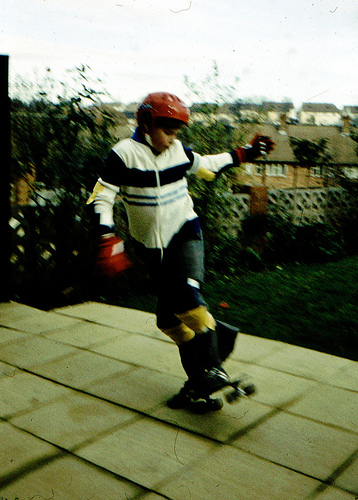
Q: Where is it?
A: This is at the backyard.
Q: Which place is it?
A: It is a backyard.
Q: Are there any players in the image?
A: No, there are no players.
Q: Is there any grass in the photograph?
A: Yes, there is grass.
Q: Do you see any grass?
A: Yes, there is grass.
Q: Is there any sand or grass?
A: Yes, there is grass.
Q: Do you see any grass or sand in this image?
A: Yes, there is grass.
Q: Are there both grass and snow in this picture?
A: No, there is grass but no snow.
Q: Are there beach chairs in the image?
A: No, there are no beach chairs.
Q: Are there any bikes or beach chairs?
A: No, there are no beach chairs or bikes.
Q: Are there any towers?
A: No, there are no towers.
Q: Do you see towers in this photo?
A: No, there are no towers.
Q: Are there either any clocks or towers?
A: No, there are no towers or clocks.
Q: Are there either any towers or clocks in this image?
A: No, there are no towers or clocks.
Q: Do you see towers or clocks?
A: No, there are no towers or clocks.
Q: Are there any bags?
A: No, there are no bags.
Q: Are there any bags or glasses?
A: No, there are no bags or glasses.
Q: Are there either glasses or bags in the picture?
A: No, there are no bags or glasses.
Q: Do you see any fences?
A: Yes, there is a fence.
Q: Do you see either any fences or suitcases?
A: Yes, there is a fence.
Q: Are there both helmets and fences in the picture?
A: Yes, there are both a fence and a helmet.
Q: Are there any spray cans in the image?
A: No, there are no spray cans.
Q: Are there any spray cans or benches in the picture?
A: No, there are no spray cans or benches.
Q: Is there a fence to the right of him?
A: Yes, there is a fence to the right of the boy.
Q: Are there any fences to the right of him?
A: Yes, there is a fence to the right of the boy.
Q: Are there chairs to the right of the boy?
A: No, there is a fence to the right of the boy.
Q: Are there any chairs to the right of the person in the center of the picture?
A: No, there is a fence to the right of the boy.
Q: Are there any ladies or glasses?
A: No, there are no glasses or ladies.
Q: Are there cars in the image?
A: No, there are no cars.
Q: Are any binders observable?
A: No, there are no binders.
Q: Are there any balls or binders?
A: No, there are no binders or balls.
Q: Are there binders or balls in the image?
A: No, there are no binders or balls.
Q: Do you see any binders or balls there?
A: No, there are no binders or balls.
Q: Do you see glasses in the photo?
A: No, there are no glasses.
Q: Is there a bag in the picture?
A: No, there are no bags.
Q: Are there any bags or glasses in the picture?
A: No, there are no bags or glasses.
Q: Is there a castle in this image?
A: No, there are no castles.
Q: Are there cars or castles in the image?
A: No, there are no castles or cars.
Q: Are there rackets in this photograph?
A: No, there are no rackets.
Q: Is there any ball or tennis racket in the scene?
A: No, there are no rackets or balls.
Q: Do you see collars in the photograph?
A: Yes, there is a collar.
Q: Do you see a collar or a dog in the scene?
A: Yes, there is a collar.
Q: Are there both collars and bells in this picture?
A: No, there is a collar but no bells.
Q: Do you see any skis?
A: No, there are no skis.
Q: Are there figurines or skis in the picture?
A: No, there are no skis or figurines.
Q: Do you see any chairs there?
A: No, there are no chairs.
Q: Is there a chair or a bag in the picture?
A: No, there are no chairs or bags.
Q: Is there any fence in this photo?
A: Yes, there is a fence.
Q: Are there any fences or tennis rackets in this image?
A: Yes, there is a fence.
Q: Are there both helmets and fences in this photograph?
A: Yes, there are both a fence and a helmet.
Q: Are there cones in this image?
A: No, there are no cones.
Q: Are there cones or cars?
A: No, there are no cones or cars.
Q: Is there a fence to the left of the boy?
A: Yes, there is a fence to the left of the boy.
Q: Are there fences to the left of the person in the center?
A: Yes, there is a fence to the left of the boy.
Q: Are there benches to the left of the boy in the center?
A: No, there is a fence to the left of the boy.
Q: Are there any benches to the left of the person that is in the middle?
A: No, there is a fence to the left of the boy.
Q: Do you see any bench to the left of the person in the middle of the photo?
A: No, there is a fence to the left of the boy.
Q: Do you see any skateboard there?
A: Yes, there is a skateboard.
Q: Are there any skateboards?
A: Yes, there is a skateboard.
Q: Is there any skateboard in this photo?
A: Yes, there is a skateboard.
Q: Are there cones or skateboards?
A: Yes, there is a skateboard.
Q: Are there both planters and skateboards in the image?
A: No, there is a skateboard but no planters.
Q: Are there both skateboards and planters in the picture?
A: No, there is a skateboard but no planters.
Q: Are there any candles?
A: No, there are no candles.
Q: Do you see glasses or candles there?
A: No, there are no candles or glasses.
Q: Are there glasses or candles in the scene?
A: No, there are no candles or glasses.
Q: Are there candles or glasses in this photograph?
A: No, there are no candles or glasses.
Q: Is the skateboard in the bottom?
A: Yes, the skateboard is in the bottom of the image.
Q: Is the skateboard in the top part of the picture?
A: No, the skateboard is in the bottom of the image.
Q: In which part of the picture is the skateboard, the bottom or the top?
A: The skateboard is in the bottom of the image.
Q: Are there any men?
A: No, there are no men.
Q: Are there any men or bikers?
A: No, there are no men or bikers.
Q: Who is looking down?
A: The boy is looking down.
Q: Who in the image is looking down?
A: The boy is looking down.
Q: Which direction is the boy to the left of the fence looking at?
A: The boy is looking down.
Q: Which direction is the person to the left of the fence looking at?
A: The boy is looking down.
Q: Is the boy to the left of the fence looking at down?
A: Yes, the boy is looking down.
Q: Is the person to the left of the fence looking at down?
A: Yes, the boy is looking down.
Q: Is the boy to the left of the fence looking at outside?
A: No, the boy is looking down.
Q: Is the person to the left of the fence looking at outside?
A: No, the boy is looking down.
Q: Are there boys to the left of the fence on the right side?
A: Yes, there is a boy to the left of the fence.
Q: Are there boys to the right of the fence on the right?
A: No, the boy is to the left of the fence.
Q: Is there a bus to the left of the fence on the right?
A: No, there is a boy to the left of the fence.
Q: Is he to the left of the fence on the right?
A: Yes, the boy is to the left of the fence.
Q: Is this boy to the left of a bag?
A: No, the boy is to the left of the fence.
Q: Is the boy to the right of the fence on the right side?
A: No, the boy is to the left of the fence.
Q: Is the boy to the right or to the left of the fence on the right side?
A: The boy is to the left of the fence.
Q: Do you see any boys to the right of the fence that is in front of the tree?
A: Yes, there is a boy to the right of the fence.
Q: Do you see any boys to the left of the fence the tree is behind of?
A: No, the boy is to the right of the fence.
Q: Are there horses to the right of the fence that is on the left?
A: No, there is a boy to the right of the fence.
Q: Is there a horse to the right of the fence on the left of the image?
A: No, there is a boy to the right of the fence.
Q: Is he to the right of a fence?
A: Yes, the boy is to the right of a fence.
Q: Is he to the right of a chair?
A: No, the boy is to the right of a fence.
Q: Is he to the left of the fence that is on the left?
A: No, the boy is to the right of the fence.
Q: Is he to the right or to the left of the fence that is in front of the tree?
A: The boy is to the right of the fence.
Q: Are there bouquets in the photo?
A: No, there are no bouquets.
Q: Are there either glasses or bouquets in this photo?
A: No, there are no bouquets or glasses.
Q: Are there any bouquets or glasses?
A: No, there are no bouquets or glasses.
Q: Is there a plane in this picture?
A: No, there are no airplanes.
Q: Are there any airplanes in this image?
A: No, there are no airplanes.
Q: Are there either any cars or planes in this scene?
A: No, there are no planes or cars.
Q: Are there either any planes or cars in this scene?
A: No, there are no planes or cars.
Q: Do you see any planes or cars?
A: No, there are no planes or cars.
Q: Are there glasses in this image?
A: No, there are no glasses.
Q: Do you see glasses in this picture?
A: No, there are no glasses.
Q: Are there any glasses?
A: No, there are no glasses.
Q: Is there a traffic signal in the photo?
A: No, there are no traffic lights.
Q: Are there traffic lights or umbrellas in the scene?
A: No, there are no traffic lights or umbrellas.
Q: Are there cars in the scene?
A: No, there are no cars.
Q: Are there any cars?
A: No, there are no cars.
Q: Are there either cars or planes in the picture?
A: No, there are no cars or planes.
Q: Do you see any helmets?
A: Yes, there is a helmet.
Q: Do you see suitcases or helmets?
A: Yes, there is a helmet.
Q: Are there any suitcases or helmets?
A: Yes, there is a helmet.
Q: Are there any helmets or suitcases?
A: Yes, there is a helmet.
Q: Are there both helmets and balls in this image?
A: No, there is a helmet but no balls.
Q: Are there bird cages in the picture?
A: No, there are no bird cages.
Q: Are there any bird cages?
A: No, there are no bird cages.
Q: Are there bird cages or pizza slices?
A: No, there are no bird cages or pizza slices.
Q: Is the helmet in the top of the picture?
A: Yes, the helmet is in the top of the image.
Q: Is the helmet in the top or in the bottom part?
A: The helmet is in the top of the image.